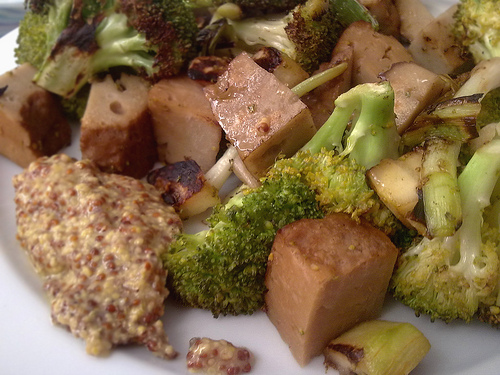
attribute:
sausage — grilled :
[330, 17, 445, 132]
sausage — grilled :
[3, 12, 471, 364]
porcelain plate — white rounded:
[0, 18, 498, 374]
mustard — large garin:
[10, 151, 253, 373]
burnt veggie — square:
[150, 157, 213, 206]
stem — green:
[321, 317, 431, 373]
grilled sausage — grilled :
[188, 43, 335, 173]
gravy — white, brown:
[51, 149, 209, 339]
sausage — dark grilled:
[261, 213, 398, 365]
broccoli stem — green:
[459, 136, 499, 226]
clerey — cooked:
[325, 305, 448, 370]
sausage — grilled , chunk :
[85, 85, 141, 161]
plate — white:
[0, 11, 499, 373]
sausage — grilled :
[211, 65, 296, 154]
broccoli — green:
[14, 17, 178, 72]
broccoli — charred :
[15, 5, 198, 96]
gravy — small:
[33, 147, 158, 297]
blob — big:
[16, 152, 181, 360]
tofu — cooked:
[244, 185, 416, 364]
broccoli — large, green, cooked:
[169, 84, 409, 317]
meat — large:
[197, 65, 335, 177]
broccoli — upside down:
[284, 81, 402, 236]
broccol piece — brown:
[42, 8, 194, 92]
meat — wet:
[198, 50, 323, 172]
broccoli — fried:
[161, 76, 498, 319]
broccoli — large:
[17, 0, 202, 104]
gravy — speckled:
[11, 151, 257, 373]